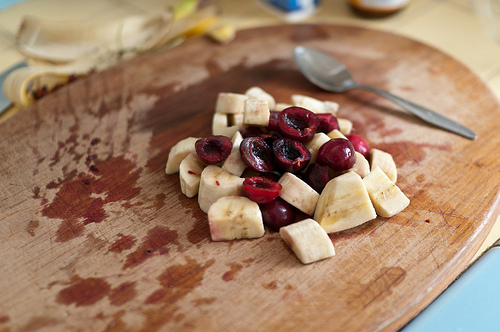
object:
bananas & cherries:
[221, 130, 274, 176]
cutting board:
[0, 23, 500, 332]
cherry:
[276, 106, 316, 140]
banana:
[315, 170, 378, 233]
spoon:
[291, 46, 476, 141]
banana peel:
[0, 3, 234, 107]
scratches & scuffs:
[435, 204, 452, 225]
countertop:
[398, 245, 500, 332]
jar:
[349, 0, 405, 20]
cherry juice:
[108, 232, 136, 252]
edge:
[353, 5, 368, 12]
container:
[261, 0, 317, 22]